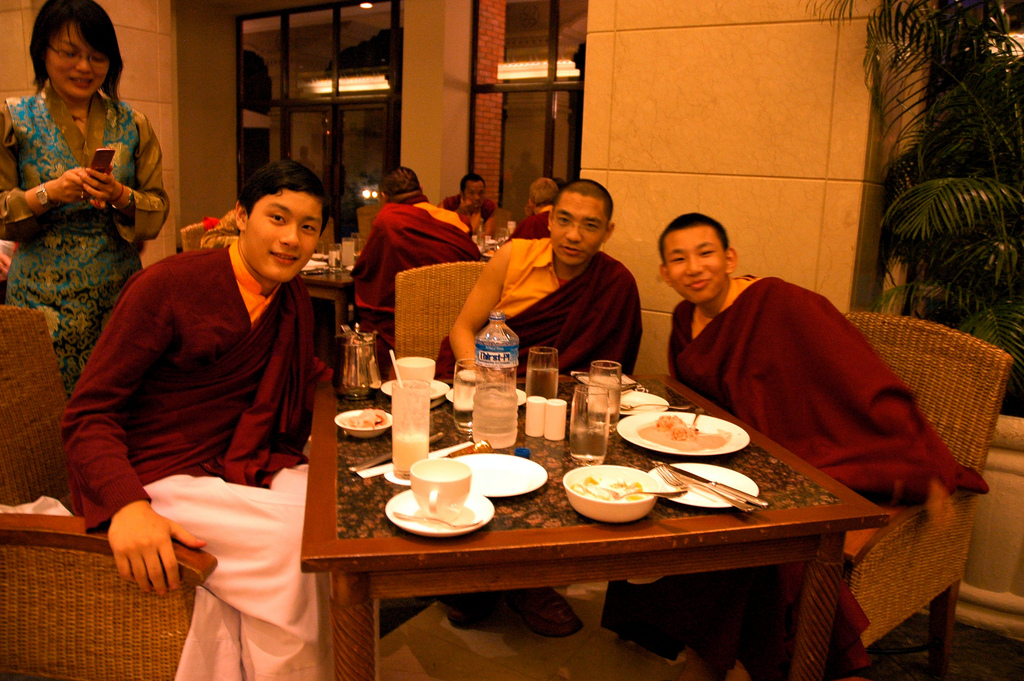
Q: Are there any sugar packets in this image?
A: No, there are no sugar packets.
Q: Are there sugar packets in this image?
A: No, there are no sugar packets.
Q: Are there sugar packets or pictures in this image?
A: No, there are no sugar packets or pictures.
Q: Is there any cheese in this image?
A: No, there is no cheese.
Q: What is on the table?
A: The dish is on the table.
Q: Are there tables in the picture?
A: Yes, there is a table.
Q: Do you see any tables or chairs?
A: Yes, there is a table.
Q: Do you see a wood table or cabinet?
A: Yes, there is a wood table.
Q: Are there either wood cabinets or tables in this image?
A: Yes, there is a wood table.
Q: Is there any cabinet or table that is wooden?
A: Yes, the table is wooden.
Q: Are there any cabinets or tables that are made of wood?
A: Yes, the table is made of wood.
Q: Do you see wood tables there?
A: Yes, there is a wood table.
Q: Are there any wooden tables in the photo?
A: Yes, there is a wood table.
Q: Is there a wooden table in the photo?
A: Yes, there is a wood table.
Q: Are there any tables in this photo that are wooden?
A: Yes, there is a table that is wooden.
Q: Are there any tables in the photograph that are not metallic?
A: Yes, there is a wooden table.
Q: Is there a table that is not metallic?
A: Yes, there is a wooden table.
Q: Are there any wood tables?
A: Yes, there is a table that is made of wood.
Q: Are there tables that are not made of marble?
A: Yes, there is a table that is made of wood.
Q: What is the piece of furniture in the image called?
A: The piece of furniture is a table.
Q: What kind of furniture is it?
A: The piece of furniture is a table.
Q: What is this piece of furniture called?
A: This is a table.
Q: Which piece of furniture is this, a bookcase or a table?
A: This is a table.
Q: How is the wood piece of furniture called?
A: The piece of furniture is a table.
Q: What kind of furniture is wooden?
A: The furniture is a table.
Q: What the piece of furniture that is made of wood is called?
A: The piece of furniture is a table.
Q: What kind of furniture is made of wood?
A: The furniture is a table.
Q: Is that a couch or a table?
A: That is a table.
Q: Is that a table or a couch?
A: That is a table.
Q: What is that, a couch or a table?
A: That is a table.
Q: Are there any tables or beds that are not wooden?
A: No, there is a table but it is wooden.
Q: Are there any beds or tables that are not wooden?
A: No, there is a table but it is wooden.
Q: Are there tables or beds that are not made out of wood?
A: No, there is a table but it is made of wood.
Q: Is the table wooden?
A: Yes, the table is wooden.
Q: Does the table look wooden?
A: Yes, the table is wooden.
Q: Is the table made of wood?
A: Yes, the table is made of wood.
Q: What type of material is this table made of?
A: The table is made of wood.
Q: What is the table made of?
A: The table is made of wood.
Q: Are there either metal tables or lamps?
A: No, there is a table but it is wooden.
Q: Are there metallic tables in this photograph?
A: No, there is a table but it is wooden.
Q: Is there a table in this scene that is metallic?
A: No, there is a table but it is wooden.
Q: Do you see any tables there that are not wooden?
A: No, there is a table but it is wooden.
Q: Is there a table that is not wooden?
A: No, there is a table but it is wooden.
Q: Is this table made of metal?
A: No, the table is made of wood.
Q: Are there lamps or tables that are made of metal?
A: No, there is a table but it is made of wood.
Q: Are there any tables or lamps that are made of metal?
A: No, there is a table but it is made of wood.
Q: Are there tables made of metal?
A: No, there is a table but it is made of wood.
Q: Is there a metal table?
A: No, there is a table but it is made of wood.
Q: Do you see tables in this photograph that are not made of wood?
A: No, there is a table but it is made of wood.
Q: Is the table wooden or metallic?
A: The table is wooden.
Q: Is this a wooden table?
A: Yes, this is a wooden table.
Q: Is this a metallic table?
A: No, this is a wooden table.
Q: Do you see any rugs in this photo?
A: No, there are no rugs.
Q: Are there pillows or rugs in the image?
A: No, there are no rugs or pillows.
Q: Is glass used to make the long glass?
A: Yes, the glass is made of glass.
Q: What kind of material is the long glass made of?
A: The glass is made of glass.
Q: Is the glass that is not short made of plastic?
A: No, the glass is made of glass.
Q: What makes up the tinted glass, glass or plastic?
A: The glass is made of glass.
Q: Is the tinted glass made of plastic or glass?
A: The glass is made of glass.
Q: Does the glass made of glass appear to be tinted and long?
A: Yes, the glass is tinted and long.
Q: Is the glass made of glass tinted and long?
A: Yes, the glass is tinted and long.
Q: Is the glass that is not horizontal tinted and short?
A: No, the glass is tinted but long.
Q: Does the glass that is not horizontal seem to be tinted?
A: Yes, the glass is tinted.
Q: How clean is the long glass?
A: The glass is tinted.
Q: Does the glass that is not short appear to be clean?
A: No, the glass is tinted.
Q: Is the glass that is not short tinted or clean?
A: The glass is tinted.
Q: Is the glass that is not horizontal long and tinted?
A: Yes, the glass is long and tinted.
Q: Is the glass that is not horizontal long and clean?
A: No, the glass is long but tinted.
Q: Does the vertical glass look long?
A: Yes, the glass is long.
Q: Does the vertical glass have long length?
A: Yes, the glass is long.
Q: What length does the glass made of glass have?
A: The glass has long length.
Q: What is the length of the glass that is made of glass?
A: The glass is long.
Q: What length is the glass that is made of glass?
A: The glass is long.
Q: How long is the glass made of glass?
A: The glass is long.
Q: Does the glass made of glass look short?
A: No, the glass is long.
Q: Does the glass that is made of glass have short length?
A: No, the glass is long.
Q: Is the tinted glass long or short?
A: The glass is long.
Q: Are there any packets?
A: No, there are no packets.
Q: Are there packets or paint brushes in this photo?
A: No, there are no packets or paint brushes.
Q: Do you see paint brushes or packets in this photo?
A: No, there are no packets or paint brushes.